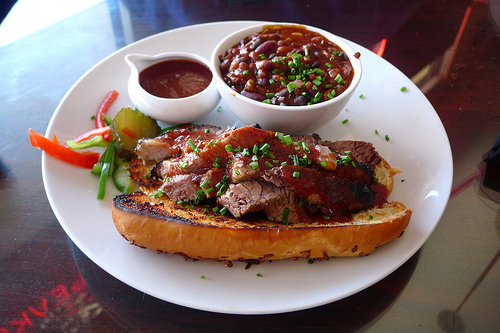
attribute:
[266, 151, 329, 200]
sauce — brown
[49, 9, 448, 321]
plate — white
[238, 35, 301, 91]
beans — brown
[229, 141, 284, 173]
parsley — green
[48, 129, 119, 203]
bell peppers — sliced